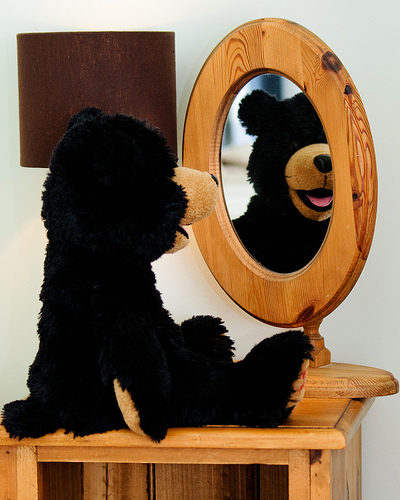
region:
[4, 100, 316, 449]
a plush teddy bear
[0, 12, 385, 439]
a plush teddy bear in front a mirror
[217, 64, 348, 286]
a plush teddy bear reflected on mirror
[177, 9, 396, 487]
a mirror on a table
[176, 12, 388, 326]
frame of mirror is wood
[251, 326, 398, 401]
the base of mirror is wood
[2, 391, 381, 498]
a table of wood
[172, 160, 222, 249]
snout of bear is brown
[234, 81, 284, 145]
round ear of bear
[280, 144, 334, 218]
tongue of bear is pink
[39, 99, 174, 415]
this is a doll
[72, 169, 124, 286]
the doll is black in color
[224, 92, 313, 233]
this is a mirror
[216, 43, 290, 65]
this is the frame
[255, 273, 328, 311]
the frame is brown in color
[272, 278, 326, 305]
the frame is wooden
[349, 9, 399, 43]
this is the wall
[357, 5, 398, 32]
the wall is white in color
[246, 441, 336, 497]
this is a cupboard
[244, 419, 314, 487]
the cupboard is wooden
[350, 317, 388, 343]
this is the wall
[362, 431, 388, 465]
the wall is white in color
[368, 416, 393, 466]
the wall is clean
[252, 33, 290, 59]
the frame is wooden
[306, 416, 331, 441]
the wood is brown in color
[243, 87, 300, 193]
this is an image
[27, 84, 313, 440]
this is a teddy bear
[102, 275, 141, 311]
the teddy is black in color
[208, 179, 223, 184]
this is the nose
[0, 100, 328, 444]
black toy bear sitting on top of table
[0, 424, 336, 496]
empty space in wooden cabinet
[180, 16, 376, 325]
reflection of smiling bear in mirror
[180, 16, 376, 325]
oval mirror in oval wooden frame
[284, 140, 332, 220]
snout with open mouth and pink tongue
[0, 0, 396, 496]
table, bear and brown shade against white wall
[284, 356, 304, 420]
red lines on bottom of tan foot pad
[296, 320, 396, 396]
carved support on oval base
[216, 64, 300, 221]
white and blue reflection in back of bear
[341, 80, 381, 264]
curved arc on frame with curved grain of wood